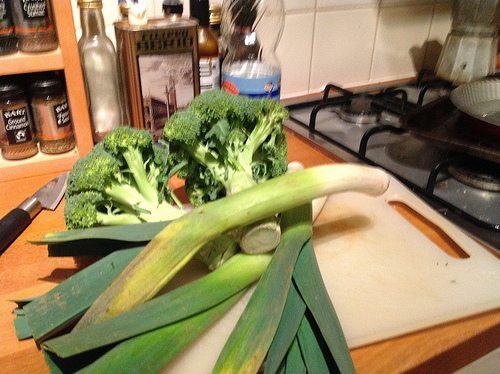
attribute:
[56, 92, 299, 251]
broccoli — large, green, lucious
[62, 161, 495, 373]
cutting board — white, plastic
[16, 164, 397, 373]
leek — large, fresh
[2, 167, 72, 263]
knife — sharp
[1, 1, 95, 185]
spice rack — wooden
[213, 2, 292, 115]
vegetable oil — bottled, empty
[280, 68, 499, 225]
stove — gas range, black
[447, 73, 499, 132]
pie pan — metal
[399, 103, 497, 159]
cookie sheet — metal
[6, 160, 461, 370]
counter — brown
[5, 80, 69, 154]
spices — plastic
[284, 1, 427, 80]
wall — white